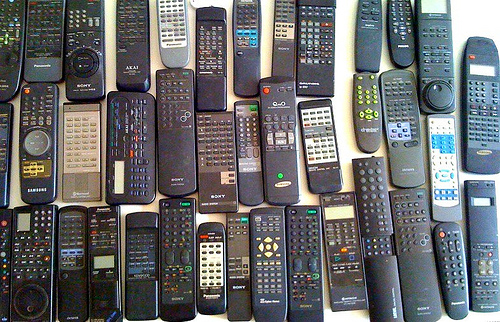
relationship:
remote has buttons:
[348, 67, 388, 154] [358, 82, 382, 136]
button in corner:
[262, 83, 275, 100] [258, 72, 275, 96]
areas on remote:
[431, 133, 456, 201] [348, 67, 388, 154]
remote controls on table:
[65, 46, 420, 280] [336, 1, 499, 196]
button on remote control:
[262, 83, 275, 100] [232, 6, 271, 94]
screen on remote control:
[324, 200, 357, 224] [232, 6, 271, 94]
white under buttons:
[304, 110, 333, 134] [358, 82, 382, 136]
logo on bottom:
[208, 192, 234, 200] [198, 190, 242, 216]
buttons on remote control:
[358, 82, 382, 136] [232, 6, 271, 94]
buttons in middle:
[358, 82, 382, 136] [254, 233, 283, 271]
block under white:
[435, 184, 462, 208] [304, 110, 333, 134]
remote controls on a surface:
[191, 65, 338, 235] [258, 2, 490, 247]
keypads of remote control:
[124, 108, 153, 173] [232, 6, 271, 94]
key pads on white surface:
[431, 119, 452, 189] [429, 118, 449, 135]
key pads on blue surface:
[431, 119, 452, 189] [435, 184, 462, 208]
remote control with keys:
[232, 6, 271, 94] [358, 79, 377, 123]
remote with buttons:
[348, 67, 388, 154] [358, 82, 382, 136]